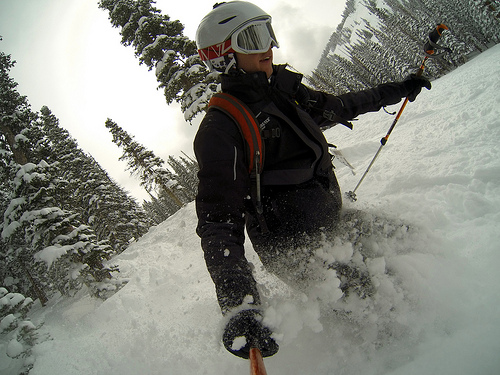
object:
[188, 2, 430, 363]
person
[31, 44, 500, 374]
snow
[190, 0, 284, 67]
helmet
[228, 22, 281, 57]
goggles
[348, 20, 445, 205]
ski pole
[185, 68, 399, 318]
jacket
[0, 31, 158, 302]
trees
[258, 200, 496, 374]
snow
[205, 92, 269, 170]
strap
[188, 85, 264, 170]
shoulder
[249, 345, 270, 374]
ski pole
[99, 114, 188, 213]
tree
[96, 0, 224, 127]
tree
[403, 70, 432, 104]
hand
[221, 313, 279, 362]
glove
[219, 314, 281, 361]
hand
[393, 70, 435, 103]
gloves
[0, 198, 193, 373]
tracks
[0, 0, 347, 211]
sky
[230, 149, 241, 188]
stripes